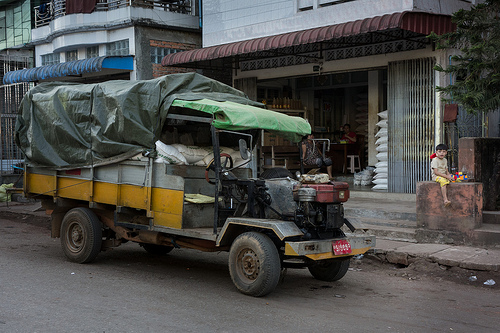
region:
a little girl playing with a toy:
[431, 140, 469, 206]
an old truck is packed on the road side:
[30, 94, 362, 284]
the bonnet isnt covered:
[224, 175, 354, 242]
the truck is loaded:
[153, 133, 211, 165]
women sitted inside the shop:
[305, 121, 360, 171]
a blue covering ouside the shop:
[0, 53, 140, 84]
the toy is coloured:
[453, 173, 471, 182]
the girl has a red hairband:
[428, 150, 439, 162]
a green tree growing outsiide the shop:
[433, 2, 498, 106]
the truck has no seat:
[169, 168, 214, 203]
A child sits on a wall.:
[426, 143, 465, 205]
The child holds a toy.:
[447, 168, 469, 182]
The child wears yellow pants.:
[433, 175, 449, 186]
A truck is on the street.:
[12, 70, 374, 295]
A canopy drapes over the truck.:
[15, 70, 266, 171]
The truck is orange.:
[27, 174, 184, 228]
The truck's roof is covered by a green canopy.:
[170, 100, 310, 135]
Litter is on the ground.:
[469, 274, 496, 286]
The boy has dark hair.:
[433, 143, 449, 150]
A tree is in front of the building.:
[425, 0, 498, 136]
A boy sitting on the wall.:
[412, 140, 473, 208]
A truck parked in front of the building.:
[48, 87, 366, 292]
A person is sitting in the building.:
[275, 123, 330, 167]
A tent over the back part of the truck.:
[33, 85, 177, 175]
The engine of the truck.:
[260, 162, 349, 222]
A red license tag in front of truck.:
[320, 228, 378, 263]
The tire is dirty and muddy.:
[213, 225, 284, 295]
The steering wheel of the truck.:
[200, 155, 245, 188]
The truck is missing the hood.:
[226, 167, 363, 244]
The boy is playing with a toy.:
[443, 165, 473, 191]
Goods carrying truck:
[30, 78, 383, 288]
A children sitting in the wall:
[423, 137, 483, 211]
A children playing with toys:
[423, 142, 473, 207]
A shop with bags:
[268, 80, 388, 179]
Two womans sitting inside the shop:
[297, 121, 363, 164]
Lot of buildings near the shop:
[11, 0, 164, 69]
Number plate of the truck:
[326, 240, 363, 256]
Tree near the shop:
[455, 15, 493, 99]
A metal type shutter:
[393, 67, 428, 165]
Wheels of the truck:
[58, 210, 283, 297]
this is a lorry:
[36, 86, 335, 326]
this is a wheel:
[232, 235, 268, 287]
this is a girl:
[420, 138, 460, 199]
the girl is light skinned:
[434, 144, 448, 159]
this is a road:
[34, 272, 81, 317]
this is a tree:
[434, 17, 497, 68]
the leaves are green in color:
[470, 37, 497, 99]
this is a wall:
[222, 10, 294, 32]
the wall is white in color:
[216, 6, 271, 28]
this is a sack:
[156, 139, 194, 174]